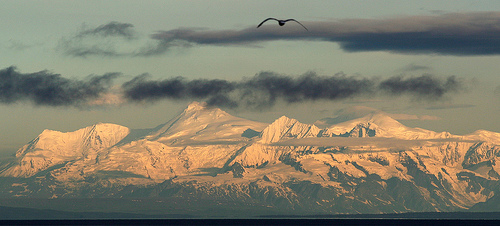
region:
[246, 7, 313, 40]
bird flying in sky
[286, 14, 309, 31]
bird wing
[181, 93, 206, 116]
top of snow covered mountain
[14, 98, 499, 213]
snow covered mountains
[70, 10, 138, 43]
grey cloud in sky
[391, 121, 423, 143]
white light reflected on snow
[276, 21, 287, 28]
body of bird in sky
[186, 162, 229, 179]
shadow on snow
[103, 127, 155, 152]
valley in snow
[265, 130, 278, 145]
line marks on side of snow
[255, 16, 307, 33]
Bird flying in sky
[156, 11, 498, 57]
Dark grey cloud in sky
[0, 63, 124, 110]
Dark grey cloud in sky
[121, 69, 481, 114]
Dark grey cloud in sky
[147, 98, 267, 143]
Snow covered mountain in background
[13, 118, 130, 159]
Snow covered mountain in background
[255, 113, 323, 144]
Snow covered mountain in background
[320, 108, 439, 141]
Snow covered mountain in background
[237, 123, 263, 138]
Shadow of a mountain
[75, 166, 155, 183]
Shadow of a mountain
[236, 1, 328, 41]
one bird in sky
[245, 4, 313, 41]
bird has wings opened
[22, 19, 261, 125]
grey and white sky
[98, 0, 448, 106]
layers of clouds in sky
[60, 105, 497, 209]
white and tall mountains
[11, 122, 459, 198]
mountains are snow covered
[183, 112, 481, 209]
white clouds cover mountain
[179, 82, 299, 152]
sharp peaks on mountain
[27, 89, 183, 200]
white and rocky mountain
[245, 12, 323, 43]
bird is dark grey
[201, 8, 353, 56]
a bird in the air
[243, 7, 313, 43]
bird is color black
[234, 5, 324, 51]
bird in front black clouds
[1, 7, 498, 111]
the sky with black clouds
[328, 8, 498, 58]
black cloud in the sky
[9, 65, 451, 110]
black cloud in the sky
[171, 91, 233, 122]
the top of a mountain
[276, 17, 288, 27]
the body of the bird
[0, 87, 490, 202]
the mountains are rocky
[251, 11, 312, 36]
bird has extended wings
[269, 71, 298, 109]
part of a cloud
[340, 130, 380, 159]
part of a cloud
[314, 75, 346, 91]
part of a cloud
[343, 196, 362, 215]
pafrt of a hill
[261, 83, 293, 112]
part of a cloud